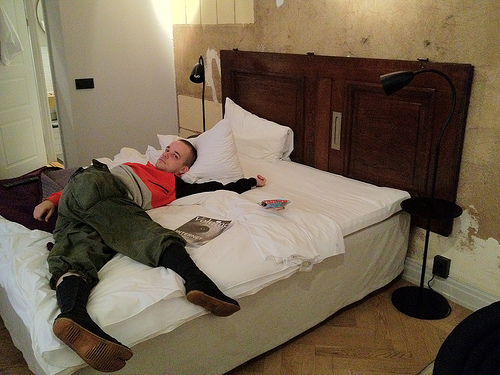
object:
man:
[32, 138, 266, 374]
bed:
[0, 129, 410, 374]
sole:
[51, 314, 134, 374]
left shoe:
[51, 274, 138, 374]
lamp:
[377, 69, 463, 322]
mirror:
[35, 1, 47, 34]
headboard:
[316, 62, 440, 164]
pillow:
[223, 97, 294, 163]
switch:
[75, 78, 95, 90]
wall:
[172, 4, 222, 42]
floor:
[338, 323, 412, 372]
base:
[391, 285, 453, 321]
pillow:
[198, 117, 244, 179]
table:
[430, 300, 500, 374]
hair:
[177, 138, 198, 169]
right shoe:
[156, 241, 242, 317]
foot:
[183, 282, 242, 318]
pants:
[45, 166, 190, 291]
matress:
[334, 187, 400, 234]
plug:
[431, 254, 451, 279]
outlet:
[431, 269, 438, 276]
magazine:
[172, 215, 234, 249]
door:
[0, 2, 47, 183]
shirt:
[41, 161, 259, 213]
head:
[155, 139, 198, 175]